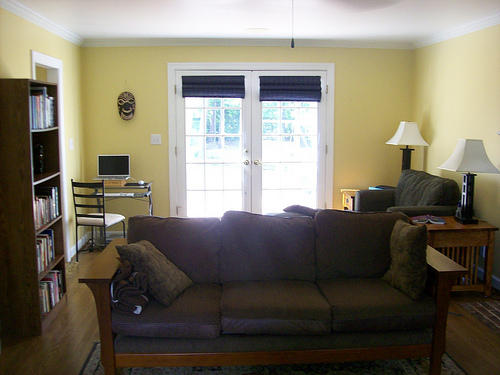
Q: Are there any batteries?
A: No, there are no batteries.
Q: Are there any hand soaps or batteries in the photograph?
A: No, there are no batteries or hand soaps.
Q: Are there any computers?
A: Yes, there is a computer.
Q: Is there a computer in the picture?
A: Yes, there is a computer.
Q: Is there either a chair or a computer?
A: Yes, there is a computer.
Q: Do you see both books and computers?
A: Yes, there are both a computer and books.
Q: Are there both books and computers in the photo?
A: Yes, there are both a computer and books.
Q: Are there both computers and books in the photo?
A: Yes, there are both a computer and books.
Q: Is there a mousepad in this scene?
A: No, there are no mouse pads.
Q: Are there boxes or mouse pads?
A: No, there are no mouse pads or boxes.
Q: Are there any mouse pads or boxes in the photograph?
A: No, there are no mouse pads or boxes.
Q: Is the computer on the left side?
A: Yes, the computer is on the left of the image.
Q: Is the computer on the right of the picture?
A: No, the computer is on the left of the image.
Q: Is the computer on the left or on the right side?
A: The computer is on the left of the image.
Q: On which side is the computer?
A: The computer is on the left of the image.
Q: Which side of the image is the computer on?
A: The computer is on the left of the image.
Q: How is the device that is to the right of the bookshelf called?
A: The device is a computer.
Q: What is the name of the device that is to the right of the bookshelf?
A: The device is a computer.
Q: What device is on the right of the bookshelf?
A: The device is a computer.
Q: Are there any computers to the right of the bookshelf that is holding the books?
A: Yes, there is a computer to the right of the bookshelf.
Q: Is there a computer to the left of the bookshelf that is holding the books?
A: No, the computer is to the right of the bookshelf.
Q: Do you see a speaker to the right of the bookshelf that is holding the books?
A: No, there is a computer to the right of the bookshelf.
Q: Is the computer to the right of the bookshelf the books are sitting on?
A: Yes, the computer is to the right of the bookshelf.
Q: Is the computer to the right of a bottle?
A: No, the computer is to the right of the bookshelf.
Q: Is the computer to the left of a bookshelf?
A: No, the computer is to the right of a bookshelf.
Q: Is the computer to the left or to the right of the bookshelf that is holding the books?
A: The computer is to the right of the bookshelf.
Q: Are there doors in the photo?
A: Yes, there are doors.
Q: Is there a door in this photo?
A: Yes, there are doors.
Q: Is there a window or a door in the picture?
A: Yes, there are doors.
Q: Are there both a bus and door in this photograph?
A: No, there are doors but no buses.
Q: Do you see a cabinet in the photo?
A: No, there are no cabinets.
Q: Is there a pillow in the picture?
A: Yes, there is a pillow.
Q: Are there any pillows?
A: Yes, there is a pillow.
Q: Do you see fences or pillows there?
A: Yes, there is a pillow.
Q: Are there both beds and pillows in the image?
A: No, there is a pillow but no beds.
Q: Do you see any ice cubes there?
A: No, there are no ice cubes.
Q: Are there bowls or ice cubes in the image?
A: No, there are no ice cubes or bowls.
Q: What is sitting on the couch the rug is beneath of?
A: The pillow is sitting on the couch.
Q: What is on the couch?
A: The pillow is on the couch.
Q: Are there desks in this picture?
A: Yes, there is a desk.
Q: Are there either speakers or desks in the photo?
A: Yes, there is a desk.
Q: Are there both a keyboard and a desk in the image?
A: No, there is a desk but no keyboards.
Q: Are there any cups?
A: No, there are no cups.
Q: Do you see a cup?
A: No, there are no cups.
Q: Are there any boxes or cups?
A: No, there are no cups or boxes.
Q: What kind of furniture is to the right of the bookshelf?
A: The piece of furniture is a desk.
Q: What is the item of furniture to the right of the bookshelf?
A: The piece of furniture is a desk.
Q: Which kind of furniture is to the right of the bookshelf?
A: The piece of furniture is a desk.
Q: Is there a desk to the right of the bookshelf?
A: Yes, there is a desk to the right of the bookshelf.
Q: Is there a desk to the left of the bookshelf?
A: No, the desk is to the right of the bookshelf.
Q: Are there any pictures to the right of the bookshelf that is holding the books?
A: No, there is a desk to the right of the bookshelf.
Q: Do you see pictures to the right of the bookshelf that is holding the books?
A: No, there is a desk to the right of the bookshelf.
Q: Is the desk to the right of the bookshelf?
A: Yes, the desk is to the right of the bookshelf.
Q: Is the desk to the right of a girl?
A: No, the desk is to the right of the bookshelf.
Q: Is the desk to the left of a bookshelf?
A: No, the desk is to the right of a bookshelf.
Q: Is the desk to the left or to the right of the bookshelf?
A: The desk is to the right of the bookshelf.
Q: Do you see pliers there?
A: No, there are no pliers.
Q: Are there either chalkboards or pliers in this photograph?
A: No, there are no pliers or chalkboards.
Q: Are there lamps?
A: Yes, there is a lamp.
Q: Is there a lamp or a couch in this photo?
A: Yes, there is a lamp.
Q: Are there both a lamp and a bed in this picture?
A: No, there is a lamp but no beds.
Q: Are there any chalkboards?
A: No, there are no chalkboards.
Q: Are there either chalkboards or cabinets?
A: No, there are no chalkboards or cabinets.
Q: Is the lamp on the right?
A: Yes, the lamp is on the right of the image.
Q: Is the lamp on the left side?
A: No, the lamp is on the right of the image.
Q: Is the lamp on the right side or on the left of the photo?
A: The lamp is on the right of the image.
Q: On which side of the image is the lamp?
A: The lamp is on the right of the image.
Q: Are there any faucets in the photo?
A: No, there are no faucets.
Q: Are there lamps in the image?
A: Yes, there is a lamp.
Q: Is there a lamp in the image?
A: Yes, there is a lamp.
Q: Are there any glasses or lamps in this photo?
A: Yes, there is a lamp.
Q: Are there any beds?
A: No, there are no beds.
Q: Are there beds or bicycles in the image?
A: No, there are no beds or bicycles.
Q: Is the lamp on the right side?
A: Yes, the lamp is on the right of the image.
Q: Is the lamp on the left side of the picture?
A: No, the lamp is on the right of the image.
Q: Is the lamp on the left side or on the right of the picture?
A: The lamp is on the right of the image.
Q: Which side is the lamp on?
A: The lamp is on the right of the image.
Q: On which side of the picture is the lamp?
A: The lamp is on the right of the image.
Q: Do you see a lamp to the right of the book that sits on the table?
A: Yes, there is a lamp to the right of the book.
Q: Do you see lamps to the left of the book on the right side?
A: No, the lamp is to the right of the book.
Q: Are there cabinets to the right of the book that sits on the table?
A: No, there is a lamp to the right of the book.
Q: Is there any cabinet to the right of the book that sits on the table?
A: No, there is a lamp to the right of the book.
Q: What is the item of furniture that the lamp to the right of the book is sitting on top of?
A: The piece of furniture is a table.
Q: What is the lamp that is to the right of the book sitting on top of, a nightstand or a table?
A: The lamp is sitting on top of a table.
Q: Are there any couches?
A: Yes, there is a couch.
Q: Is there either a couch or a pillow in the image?
A: Yes, there is a couch.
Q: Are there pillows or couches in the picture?
A: Yes, there is a couch.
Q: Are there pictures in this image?
A: No, there are no pictures.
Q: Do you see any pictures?
A: No, there are no pictures.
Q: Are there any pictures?
A: No, there are no pictures.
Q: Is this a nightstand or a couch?
A: This is a couch.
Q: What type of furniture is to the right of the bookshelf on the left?
A: The piece of furniture is a couch.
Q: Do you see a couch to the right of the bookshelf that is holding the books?
A: Yes, there is a couch to the right of the bookshelf.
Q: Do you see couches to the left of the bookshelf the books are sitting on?
A: No, the couch is to the right of the bookshelf.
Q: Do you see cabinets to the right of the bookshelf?
A: No, there is a couch to the right of the bookshelf.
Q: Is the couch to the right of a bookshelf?
A: Yes, the couch is to the right of a bookshelf.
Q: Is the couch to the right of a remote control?
A: No, the couch is to the right of a bookshelf.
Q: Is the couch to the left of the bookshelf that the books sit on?
A: No, the couch is to the right of the bookshelf.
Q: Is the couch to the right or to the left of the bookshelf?
A: The couch is to the right of the bookshelf.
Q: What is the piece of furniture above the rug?
A: The piece of furniture is a couch.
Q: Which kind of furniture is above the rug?
A: The piece of furniture is a couch.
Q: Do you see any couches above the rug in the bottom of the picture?
A: Yes, there is a couch above the rug.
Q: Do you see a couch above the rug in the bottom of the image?
A: Yes, there is a couch above the rug.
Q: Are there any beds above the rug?
A: No, there is a couch above the rug.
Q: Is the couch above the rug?
A: Yes, the couch is above the rug.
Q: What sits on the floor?
A: The couch sits on the floor.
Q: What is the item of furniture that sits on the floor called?
A: The piece of furniture is a couch.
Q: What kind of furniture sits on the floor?
A: The piece of furniture is a couch.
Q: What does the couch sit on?
A: The couch sits on the floor.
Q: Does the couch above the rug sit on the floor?
A: Yes, the couch sits on the floor.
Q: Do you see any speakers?
A: No, there are no speakers.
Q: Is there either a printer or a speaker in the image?
A: No, there are no speakers or printers.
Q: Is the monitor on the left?
A: Yes, the monitor is on the left of the image.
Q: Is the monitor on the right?
A: No, the monitor is on the left of the image.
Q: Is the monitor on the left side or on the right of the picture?
A: The monitor is on the left of the image.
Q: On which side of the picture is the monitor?
A: The monitor is on the left of the image.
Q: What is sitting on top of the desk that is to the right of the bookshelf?
A: The monitor is sitting on top of the desk.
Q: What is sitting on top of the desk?
A: The monitor is sitting on top of the desk.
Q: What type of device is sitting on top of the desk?
A: The device is a monitor.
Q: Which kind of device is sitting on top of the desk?
A: The device is a monitor.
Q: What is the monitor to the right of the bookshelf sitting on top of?
A: The monitor is sitting on top of the desk.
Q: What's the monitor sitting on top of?
A: The monitor is sitting on top of the desk.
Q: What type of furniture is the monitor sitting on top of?
A: The monitor is sitting on top of the desk.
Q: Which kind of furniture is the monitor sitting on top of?
A: The monitor is sitting on top of the desk.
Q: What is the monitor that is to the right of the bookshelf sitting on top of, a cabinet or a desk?
A: The monitor is sitting on top of a desk.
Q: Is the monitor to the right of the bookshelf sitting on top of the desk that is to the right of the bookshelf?
A: Yes, the monitor is sitting on top of the desk.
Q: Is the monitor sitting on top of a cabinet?
A: No, the monitor is sitting on top of the desk.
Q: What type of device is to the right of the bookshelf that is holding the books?
A: The device is a monitor.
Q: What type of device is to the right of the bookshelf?
A: The device is a monitor.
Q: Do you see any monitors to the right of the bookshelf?
A: Yes, there is a monitor to the right of the bookshelf.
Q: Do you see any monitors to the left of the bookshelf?
A: No, the monitor is to the right of the bookshelf.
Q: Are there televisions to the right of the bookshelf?
A: No, there is a monitor to the right of the bookshelf.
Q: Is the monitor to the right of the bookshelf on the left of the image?
A: Yes, the monitor is to the right of the bookshelf.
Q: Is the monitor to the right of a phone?
A: No, the monitor is to the right of the bookshelf.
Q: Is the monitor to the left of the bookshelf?
A: No, the monitor is to the right of the bookshelf.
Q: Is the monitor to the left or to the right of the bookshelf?
A: The monitor is to the right of the bookshelf.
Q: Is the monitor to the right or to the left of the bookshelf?
A: The monitor is to the right of the bookshelf.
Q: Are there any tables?
A: Yes, there is a table.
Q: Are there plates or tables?
A: Yes, there is a table.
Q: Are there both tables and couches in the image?
A: Yes, there are both a table and a couch.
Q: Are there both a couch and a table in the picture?
A: Yes, there are both a table and a couch.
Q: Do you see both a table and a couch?
A: Yes, there are both a table and a couch.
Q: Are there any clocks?
A: No, there are no clocks.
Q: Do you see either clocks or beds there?
A: No, there are no clocks or beds.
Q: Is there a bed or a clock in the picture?
A: No, there are no clocks or beds.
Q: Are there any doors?
A: Yes, there is a door.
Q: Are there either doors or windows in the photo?
A: Yes, there is a door.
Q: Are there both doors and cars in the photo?
A: No, there is a door but no cars.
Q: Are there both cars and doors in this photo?
A: No, there is a door but no cars.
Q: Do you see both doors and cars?
A: No, there is a door but no cars.